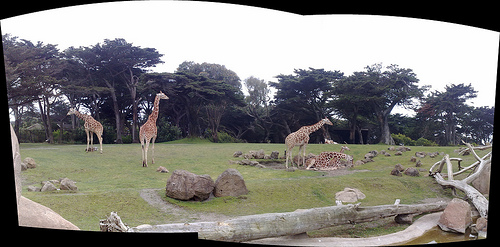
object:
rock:
[165, 169, 216, 200]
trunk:
[127, 202, 463, 243]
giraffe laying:
[304, 146, 350, 171]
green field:
[20, 142, 496, 229]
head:
[67, 107, 78, 116]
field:
[17, 143, 492, 243]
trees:
[3, 30, 494, 148]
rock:
[21, 158, 35, 169]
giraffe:
[283, 116, 333, 170]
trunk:
[44, 109, 54, 144]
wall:
[242, 76, 332, 129]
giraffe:
[137, 92, 170, 167]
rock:
[155, 166, 169, 173]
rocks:
[25, 176, 77, 193]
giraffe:
[67, 106, 106, 153]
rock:
[388, 164, 405, 176]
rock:
[240, 159, 259, 165]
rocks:
[357, 145, 440, 166]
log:
[204, 179, 451, 241]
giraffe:
[297, 144, 361, 170]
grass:
[20, 140, 483, 240]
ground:
[7, 150, 472, 240]